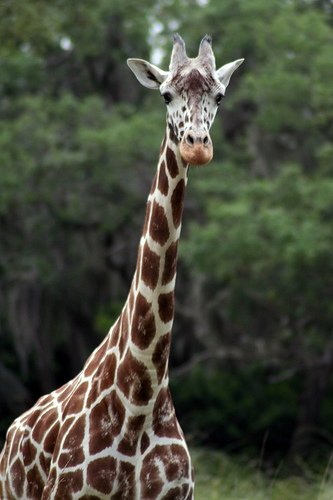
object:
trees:
[13, 19, 109, 312]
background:
[8, 12, 327, 417]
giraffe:
[0, 33, 249, 495]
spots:
[86, 453, 121, 495]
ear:
[124, 55, 163, 91]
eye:
[162, 91, 173, 106]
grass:
[196, 454, 330, 500]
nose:
[185, 127, 210, 152]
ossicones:
[168, 31, 190, 67]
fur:
[155, 206, 180, 240]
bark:
[194, 303, 234, 365]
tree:
[254, 167, 329, 423]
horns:
[195, 31, 218, 67]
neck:
[121, 160, 196, 337]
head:
[124, 33, 246, 161]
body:
[0, 370, 195, 500]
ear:
[217, 53, 248, 87]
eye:
[213, 90, 224, 107]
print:
[89, 370, 129, 460]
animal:
[0, 36, 253, 496]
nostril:
[202, 134, 210, 149]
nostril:
[186, 130, 196, 149]